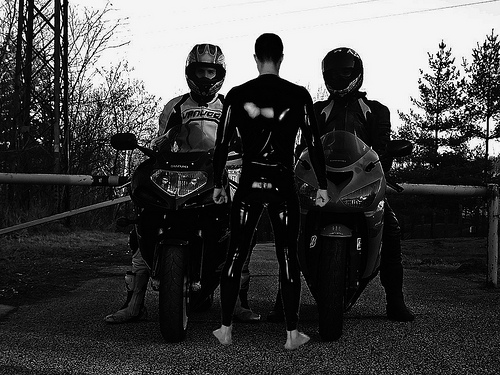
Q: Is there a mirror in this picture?
A: Yes, there is a mirror.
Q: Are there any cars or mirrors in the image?
A: Yes, there is a mirror.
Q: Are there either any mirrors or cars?
A: Yes, there is a mirror.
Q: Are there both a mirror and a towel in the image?
A: No, there is a mirror but no towels.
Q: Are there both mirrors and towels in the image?
A: No, there is a mirror but no towels.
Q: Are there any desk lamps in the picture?
A: No, there are no desk lamps.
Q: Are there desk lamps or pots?
A: No, there are no desk lamps or pots.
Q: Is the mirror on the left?
A: Yes, the mirror is on the left of the image.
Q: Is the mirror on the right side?
A: No, the mirror is on the left of the image.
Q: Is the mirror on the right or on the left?
A: The mirror is on the left of the image.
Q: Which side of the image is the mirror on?
A: The mirror is on the left of the image.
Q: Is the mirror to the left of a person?
A: Yes, the mirror is to the left of a person.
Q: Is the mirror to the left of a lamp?
A: No, the mirror is to the left of a person.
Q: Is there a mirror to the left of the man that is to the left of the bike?
A: Yes, there is a mirror to the left of the man.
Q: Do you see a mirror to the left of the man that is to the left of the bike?
A: Yes, there is a mirror to the left of the man.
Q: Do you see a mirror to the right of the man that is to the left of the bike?
A: No, the mirror is to the left of the man.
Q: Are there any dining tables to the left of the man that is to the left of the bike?
A: No, there is a mirror to the left of the man.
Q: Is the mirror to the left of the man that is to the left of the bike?
A: Yes, the mirror is to the left of the man.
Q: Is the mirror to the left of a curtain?
A: No, the mirror is to the left of the man.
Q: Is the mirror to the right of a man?
A: No, the mirror is to the left of a man.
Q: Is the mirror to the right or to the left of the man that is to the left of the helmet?
A: The mirror is to the left of the man.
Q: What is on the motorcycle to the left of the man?
A: The mirror is on the motorcycle.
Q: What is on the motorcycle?
A: The mirror is on the motorcycle.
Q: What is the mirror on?
A: The mirror is on the motorbike.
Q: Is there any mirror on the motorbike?
A: Yes, there is a mirror on the motorbike.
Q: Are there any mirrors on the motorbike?
A: Yes, there is a mirror on the motorbike.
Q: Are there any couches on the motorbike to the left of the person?
A: No, there is a mirror on the motorcycle.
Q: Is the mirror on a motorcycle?
A: Yes, the mirror is on a motorcycle.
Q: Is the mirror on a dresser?
A: No, the mirror is on a motorcycle.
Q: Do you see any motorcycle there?
A: Yes, there is a motorcycle.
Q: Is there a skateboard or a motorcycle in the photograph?
A: Yes, there is a motorcycle.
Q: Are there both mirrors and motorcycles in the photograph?
A: Yes, there are both a motorcycle and a mirror.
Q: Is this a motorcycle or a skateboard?
A: This is a motorcycle.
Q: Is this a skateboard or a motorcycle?
A: This is a motorcycle.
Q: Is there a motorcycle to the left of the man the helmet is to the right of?
A: Yes, there is a motorcycle to the left of the man.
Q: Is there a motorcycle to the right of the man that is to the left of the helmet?
A: No, the motorcycle is to the left of the man.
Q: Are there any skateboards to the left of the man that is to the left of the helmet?
A: No, there is a motorcycle to the left of the man.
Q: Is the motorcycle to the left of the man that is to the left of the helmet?
A: Yes, the motorcycle is to the left of the man.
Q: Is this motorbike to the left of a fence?
A: No, the motorbike is to the left of the man.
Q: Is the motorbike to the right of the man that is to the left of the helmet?
A: No, the motorbike is to the left of the man.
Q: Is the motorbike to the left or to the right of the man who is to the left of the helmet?
A: The motorbike is to the left of the man.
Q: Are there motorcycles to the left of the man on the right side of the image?
A: Yes, there is a motorcycle to the left of the man.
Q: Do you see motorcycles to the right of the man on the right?
A: No, the motorcycle is to the left of the man.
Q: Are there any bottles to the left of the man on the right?
A: No, there is a motorcycle to the left of the man.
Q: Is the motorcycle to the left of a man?
A: Yes, the motorcycle is to the left of a man.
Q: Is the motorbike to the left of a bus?
A: No, the motorbike is to the left of a man.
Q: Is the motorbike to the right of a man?
A: No, the motorbike is to the left of a man.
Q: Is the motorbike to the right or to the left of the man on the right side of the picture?
A: The motorbike is to the left of the man.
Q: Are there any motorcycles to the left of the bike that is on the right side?
A: Yes, there is a motorcycle to the left of the bike.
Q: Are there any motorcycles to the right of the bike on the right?
A: No, the motorcycle is to the left of the bike.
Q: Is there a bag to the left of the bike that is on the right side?
A: No, there is a motorcycle to the left of the bike.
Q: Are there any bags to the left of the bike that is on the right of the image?
A: No, there is a motorcycle to the left of the bike.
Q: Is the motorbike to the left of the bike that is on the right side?
A: Yes, the motorbike is to the left of the bike.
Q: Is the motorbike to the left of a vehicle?
A: No, the motorbike is to the left of the bike.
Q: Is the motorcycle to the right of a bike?
A: No, the motorcycle is to the left of a bike.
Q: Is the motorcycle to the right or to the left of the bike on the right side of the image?
A: The motorcycle is to the left of the bike.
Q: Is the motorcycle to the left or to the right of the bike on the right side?
A: The motorcycle is to the left of the bike.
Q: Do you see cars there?
A: No, there are no cars.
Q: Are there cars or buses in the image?
A: No, there are no cars or buses.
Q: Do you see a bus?
A: No, there are no buses.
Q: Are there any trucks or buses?
A: No, there are no buses or trucks.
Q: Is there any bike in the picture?
A: Yes, there is a bike.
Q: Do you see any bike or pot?
A: Yes, there is a bike.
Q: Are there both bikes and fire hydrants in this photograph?
A: No, there is a bike but no fire hydrants.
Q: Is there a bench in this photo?
A: No, there are no benches.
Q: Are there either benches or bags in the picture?
A: No, there are no benches or bags.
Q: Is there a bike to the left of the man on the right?
A: Yes, there is a bike to the left of the man.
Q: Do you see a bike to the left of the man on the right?
A: Yes, there is a bike to the left of the man.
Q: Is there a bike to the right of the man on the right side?
A: No, the bike is to the left of the man.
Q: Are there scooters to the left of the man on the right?
A: No, there is a bike to the left of the man.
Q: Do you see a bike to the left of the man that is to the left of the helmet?
A: Yes, there is a bike to the left of the man.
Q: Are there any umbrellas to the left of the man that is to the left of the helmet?
A: No, there is a bike to the left of the man.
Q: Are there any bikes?
A: Yes, there is a bike.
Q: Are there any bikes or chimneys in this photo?
A: Yes, there is a bike.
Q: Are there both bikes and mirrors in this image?
A: Yes, there are both a bike and a mirror.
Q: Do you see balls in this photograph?
A: No, there are no balls.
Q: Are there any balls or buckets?
A: No, there are no balls or buckets.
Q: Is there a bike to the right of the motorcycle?
A: Yes, there is a bike to the right of the motorcycle.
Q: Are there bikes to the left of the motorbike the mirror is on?
A: No, the bike is to the right of the motorcycle.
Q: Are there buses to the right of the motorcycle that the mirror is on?
A: No, there is a bike to the right of the motorbike.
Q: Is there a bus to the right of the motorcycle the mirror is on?
A: No, there is a bike to the right of the motorbike.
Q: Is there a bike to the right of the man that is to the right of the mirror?
A: Yes, there is a bike to the right of the man.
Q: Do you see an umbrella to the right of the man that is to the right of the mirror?
A: No, there is a bike to the right of the man.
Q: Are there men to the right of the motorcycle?
A: Yes, there is a man to the right of the motorcycle.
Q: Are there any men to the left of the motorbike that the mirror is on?
A: No, the man is to the right of the motorbike.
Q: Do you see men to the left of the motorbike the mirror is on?
A: No, the man is to the right of the motorbike.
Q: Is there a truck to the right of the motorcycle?
A: No, there is a man to the right of the motorcycle.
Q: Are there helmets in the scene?
A: Yes, there is a helmet.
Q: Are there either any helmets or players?
A: Yes, there is a helmet.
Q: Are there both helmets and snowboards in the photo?
A: No, there is a helmet but no snowboards.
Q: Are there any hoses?
A: No, there are no hoses.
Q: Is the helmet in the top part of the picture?
A: Yes, the helmet is in the top of the image.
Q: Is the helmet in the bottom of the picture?
A: No, the helmet is in the top of the image.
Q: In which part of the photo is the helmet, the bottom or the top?
A: The helmet is in the top of the image.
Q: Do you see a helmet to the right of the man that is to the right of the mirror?
A: Yes, there is a helmet to the right of the man.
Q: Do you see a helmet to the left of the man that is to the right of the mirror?
A: No, the helmet is to the right of the man.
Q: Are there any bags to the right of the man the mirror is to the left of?
A: No, there is a helmet to the right of the man.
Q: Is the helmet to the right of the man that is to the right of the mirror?
A: Yes, the helmet is to the right of the man.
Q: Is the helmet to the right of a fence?
A: No, the helmet is to the right of the man.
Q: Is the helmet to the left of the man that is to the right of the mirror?
A: No, the helmet is to the right of the man.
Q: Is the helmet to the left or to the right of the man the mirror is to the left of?
A: The helmet is to the right of the man.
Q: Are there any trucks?
A: No, there are no trucks.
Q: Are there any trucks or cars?
A: No, there are no trucks or cars.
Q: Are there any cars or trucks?
A: No, there are no trucks or cars.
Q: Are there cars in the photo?
A: No, there are no cars.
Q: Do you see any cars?
A: No, there are no cars.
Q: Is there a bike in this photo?
A: Yes, there are bikes.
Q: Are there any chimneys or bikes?
A: Yes, there are bikes.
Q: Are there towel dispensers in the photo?
A: No, there are no towel dispensers.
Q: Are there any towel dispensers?
A: No, there are no towel dispensers.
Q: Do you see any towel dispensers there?
A: No, there are no towel dispensers.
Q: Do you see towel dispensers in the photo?
A: No, there are no towel dispensers.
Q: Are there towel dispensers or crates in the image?
A: No, there are no towel dispensers or crates.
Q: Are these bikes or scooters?
A: These are bikes.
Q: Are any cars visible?
A: No, there are no cars.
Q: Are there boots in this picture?
A: Yes, there are boots.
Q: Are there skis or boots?
A: Yes, there are boots.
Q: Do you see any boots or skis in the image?
A: Yes, there are boots.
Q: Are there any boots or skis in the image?
A: Yes, there are boots.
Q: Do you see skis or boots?
A: Yes, there are boots.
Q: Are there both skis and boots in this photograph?
A: No, there are boots but no skis.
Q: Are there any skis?
A: No, there are no skis.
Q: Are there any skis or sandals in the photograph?
A: No, there are no skis or sandals.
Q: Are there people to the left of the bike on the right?
A: Yes, there is a person to the left of the bike.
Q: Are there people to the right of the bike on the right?
A: No, the person is to the left of the bike.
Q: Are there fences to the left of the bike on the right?
A: No, there is a person to the left of the bike.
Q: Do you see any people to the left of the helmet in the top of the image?
A: Yes, there is a person to the left of the helmet.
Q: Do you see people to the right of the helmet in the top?
A: No, the person is to the left of the helmet.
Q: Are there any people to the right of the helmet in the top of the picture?
A: No, the person is to the left of the helmet.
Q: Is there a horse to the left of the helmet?
A: No, there is a person to the left of the helmet.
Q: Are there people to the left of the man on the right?
A: Yes, there is a person to the left of the man.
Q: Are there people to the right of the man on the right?
A: No, the person is to the left of the man.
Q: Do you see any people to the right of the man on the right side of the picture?
A: No, the person is to the left of the man.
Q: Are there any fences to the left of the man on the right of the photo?
A: No, there is a person to the left of the man.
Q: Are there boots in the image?
A: Yes, there are boots.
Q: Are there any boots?
A: Yes, there are boots.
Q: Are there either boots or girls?
A: Yes, there are boots.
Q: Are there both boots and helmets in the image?
A: Yes, there are both boots and a helmet.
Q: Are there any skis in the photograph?
A: No, there are no skis.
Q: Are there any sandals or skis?
A: No, there are no skis or sandals.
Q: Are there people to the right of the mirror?
A: Yes, there is a person to the right of the mirror.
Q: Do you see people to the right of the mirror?
A: Yes, there is a person to the right of the mirror.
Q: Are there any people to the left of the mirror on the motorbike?
A: No, the person is to the right of the mirror.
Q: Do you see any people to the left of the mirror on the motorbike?
A: No, the person is to the right of the mirror.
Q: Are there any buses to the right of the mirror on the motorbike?
A: No, there is a person to the right of the mirror.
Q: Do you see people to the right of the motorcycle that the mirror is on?
A: Yes, there is a person to the right of the motorbike.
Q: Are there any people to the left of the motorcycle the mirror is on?
A: No, the person is to the right of the motorcycle.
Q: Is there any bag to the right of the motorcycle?
A: No, there is a person to the right of the motorcycle.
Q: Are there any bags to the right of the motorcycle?
A: No, there is a person to the right of the motorcycle.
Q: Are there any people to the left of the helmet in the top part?
A: Yes, there is a person to the left of the helmet.